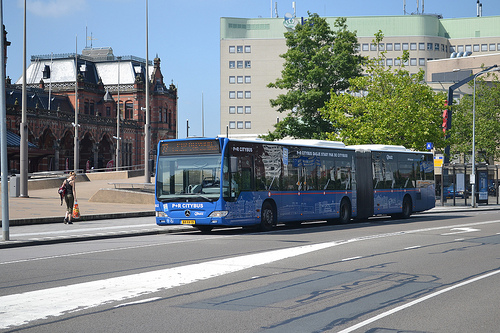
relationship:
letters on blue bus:
[164, 196, 212, 212] [154, 137, 436, 231]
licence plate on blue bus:
[181, 220, 196, 225] [154, 137, 436, 231]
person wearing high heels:
[58, 171, 78, 224] [62, 218, 72, 225]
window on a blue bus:
[157, 152, 229, 202] [154, 137, 436, 231]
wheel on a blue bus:
[242, 198, 278, 232] [154, 137, 436, 231]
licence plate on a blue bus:
[181, 220, 196, 225] [154, 137, 436, 231]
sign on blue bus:
[150, 137, 220, 153] [154, 137, 436, 231]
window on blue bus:
[151, 152, 225, 204] [154, 137, 436, 231]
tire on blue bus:
[243, 198, 278, 232] [154, 137, 436, 231]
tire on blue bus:
[328, 196, 352, 225] [154, 137, 436, 231]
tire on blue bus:
[391, 193, 412, 220] [154, 137, 436, 231]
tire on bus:
[331, 188, 357, 225] [159, 130, 471, 239]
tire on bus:
[239, 191, 295, 232] [159, 130, 471, 239]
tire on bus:
[388, 180, 437, 236] [159, 130, 471, 239]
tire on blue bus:
[335, 190, 364, 230] [154, 137, 436, 231]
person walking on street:
[58, 171, 78, 224] [0, 167, 182, 267]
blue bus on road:
[154, 137, 436, 231] [120, 223, 345, 317]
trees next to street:
[257, 9, 499, 159] [2, 202, 499, 332]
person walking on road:
[58, 171, 78, 224] [278, 247, 498, 325]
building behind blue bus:
[10, 30, 184, 190] [154, 137, 436, 231]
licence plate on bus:
[170, 210, 210, 237] [161, 140, 436, 223]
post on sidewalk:
[465, 61, 499, 212] [421, 164, 499, 204]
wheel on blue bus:
[255, 195, 279, 231] [154, 137, 436, 231]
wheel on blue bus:
[328, 191, 357, 227] [154, 137, 436, 231]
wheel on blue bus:
[397, 190, 419, 221] [154, 137, 436, 231]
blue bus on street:
[154, 137, 436, 231] [2, 202, 499, 332]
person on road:
[55, 168, 82, 225] [64, 230, 468, 330]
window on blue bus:
[373, 162, 435, 190] [154, 137, 436, 231]